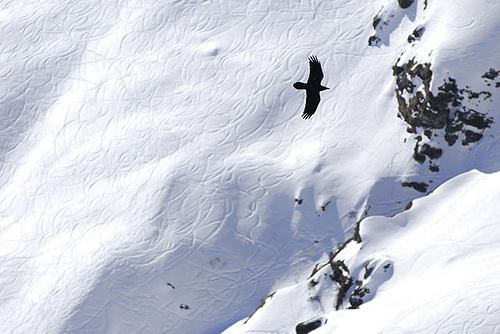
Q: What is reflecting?
A: Sunshine on snow.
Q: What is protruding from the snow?
A: Rocks.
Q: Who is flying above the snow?
A: Large bird.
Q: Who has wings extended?
A: Large bird.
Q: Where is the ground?
A: Beneath the snow.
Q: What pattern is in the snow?
A: Swirl pattern.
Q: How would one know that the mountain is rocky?
A: Rocky protrusion is visible.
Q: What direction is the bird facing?
A: Right.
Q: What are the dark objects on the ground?
A: Rocks.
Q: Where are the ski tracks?
A: In snow.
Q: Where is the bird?
A: In the air.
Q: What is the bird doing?
A: Flying.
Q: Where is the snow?
A: On ground.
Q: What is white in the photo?
A: Snow.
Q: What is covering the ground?
A: Snow.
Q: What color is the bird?
A: Black.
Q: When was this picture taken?
A: Daytime.